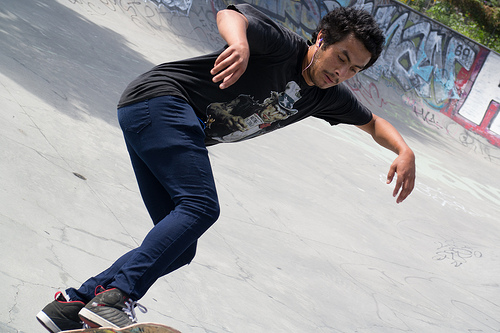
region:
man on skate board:
[74, 15, 429, 308]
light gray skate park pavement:
[266, 203, 316, 273]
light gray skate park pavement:
[337, 275, 349, 297]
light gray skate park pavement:
[407, 256, 443, 303]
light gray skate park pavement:
[219, 297, 258, 329]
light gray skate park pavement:
[71, 167, 114, 216]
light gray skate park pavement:
[18, 116, 52, 152]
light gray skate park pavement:
[264, 248, 319, 298]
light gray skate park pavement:
[381, 250, 413, 296]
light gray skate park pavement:
[429, 215, 484, 250]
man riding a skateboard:
[89, 5, 452, 265]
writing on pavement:
[422, 227, 483, 274]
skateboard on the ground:
[82, 315, 169, 332]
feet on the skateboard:
[37, 270, 135, 327]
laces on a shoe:
[120, 299, 149, 321]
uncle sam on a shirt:
[253, 70, 301, 131]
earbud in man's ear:
[303, 25, 323, 80]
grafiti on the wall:
[420, 23, 490, 119]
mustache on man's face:
[323, 61, 335, 82]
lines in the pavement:
[335, 240, 439, 321]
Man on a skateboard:
[40, 2, 417, 332]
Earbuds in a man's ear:
[297, 27, 322, 86]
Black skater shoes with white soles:
[32, 281, 151, 331]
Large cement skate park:
[0, 0, 497, 331]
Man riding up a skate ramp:
[37, 3, 417, 330]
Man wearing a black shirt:
[33, 2, 416, 332]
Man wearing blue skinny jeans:
[34, 3, 419, 332]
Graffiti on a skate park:
[70, 0, 498, 165]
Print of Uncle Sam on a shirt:
[201, 78, 303, 145]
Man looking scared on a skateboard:
[37, 3, 419, 331]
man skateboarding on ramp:
[35, 9, 415, 331]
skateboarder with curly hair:
[39, 9, 415, 331]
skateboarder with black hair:
[39, 4, 415, 331]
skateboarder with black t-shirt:
[34, 1, 415, 328]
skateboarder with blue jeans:
[35, 7, 415, 330]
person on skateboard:
[31, 6, 415, 332]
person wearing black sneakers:
[35, 5, 417, 331]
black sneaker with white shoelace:
[80, 285, 145, 330]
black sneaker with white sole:
[37, 289, 87, 331]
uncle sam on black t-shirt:
[114, 0, 373, 148]